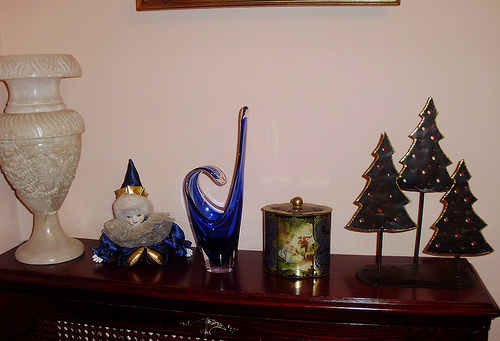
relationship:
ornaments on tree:
[437, 170, 479, 254] [422, 160, 495, 260]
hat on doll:
[115, 158, 149, 197] [92, 158, 194, 267]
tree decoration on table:
[344, 96, 493, 287] [2, 237, 497, 316]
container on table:
[261, 195, 331, 279] [2, 237, 497, 316]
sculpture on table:
[183, 106, 250, 273] [2, 237, 497, 316]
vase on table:
[0, 53, 85, 265] [2, 237, 497, 316]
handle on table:
[174, 317, 240, 339] [2, 237, 497, 316]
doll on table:
[92, 158, 194, 267] [2, 237, 497, 316]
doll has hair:
[92, 158, 194, 267] [113, 194, 153, 215]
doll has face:
[92, 158, 194, 267] [125, 212, 145, 226]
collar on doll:
[100, 212, 173, 246] [92, 158, 194, 267]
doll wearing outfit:
[92, 158, 194, 267] [95, 219, 191, 265]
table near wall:
[2, 237, 497, 316] [3, 5, 498, 257]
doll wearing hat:
[92, 158, 194, 267] [115, 158, 149, 197]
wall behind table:
[3, 5, 498, 257] [2, 237, 497, 316]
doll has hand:
[92, 158, 194, 267] [91, 252, 104, 263]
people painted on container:
[276, 232, 312, 266] [261, 195, 331, 279]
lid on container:
[261, 195, 333, 217] [261, 195, 331, 279]